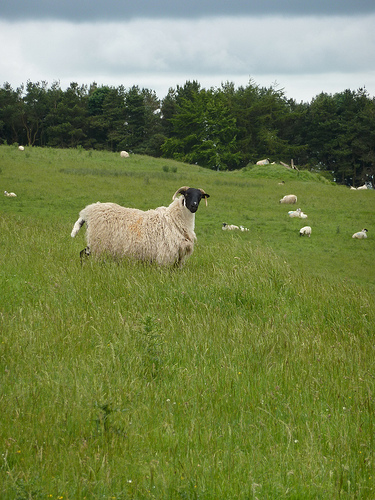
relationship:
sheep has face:
[71, 183, 211, 264] [179, 188, 204, 214]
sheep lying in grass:
[350, 225, 370, 239] [2, 143, 374, 498]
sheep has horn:
[71, 183, 211, 264] [171, 184, 185, 202]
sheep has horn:
[71, 183, 211, 264] [199, 187, 209, 210]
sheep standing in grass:
[71, 183, 211, 264] [2, 143, 374, 498]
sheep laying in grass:
[350, 225, 370, 239] [2, 143, 374, 498]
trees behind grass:
[1, 77, 374, 189] [2, 143, 374, 498]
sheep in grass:
[71, 183, 211, 264] [2, 143, 374, 498]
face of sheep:
[179, 188, 204, 214] [71, 183, 211, 264]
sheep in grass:
[350, 225, 370, 239] [2, 143, 374, 498]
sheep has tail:
[71, 183, 211, 264] [69, 215, 88, 239]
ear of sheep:
[178, 189, 188, 197] [71, 183, 211, 264]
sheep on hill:
[350, 225, 370, 239] [0, 141, 372, 497]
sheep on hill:
[278, 191, 298, 205] [0, 141, 372, 497]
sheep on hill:
[295, 223, 313, 239] [0, 141, 372, 497]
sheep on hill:
[278, 191, 298, 205] [3, 84, 373, 497]